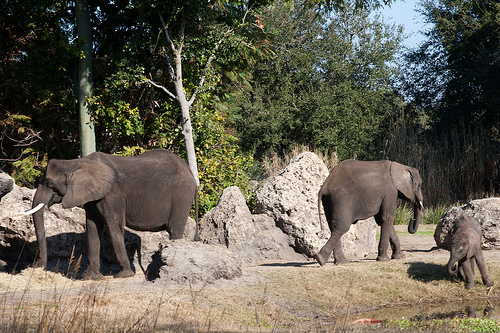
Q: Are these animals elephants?
A: Yes, all the animals are elephants.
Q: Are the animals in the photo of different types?
A: No, all the animals are elephants.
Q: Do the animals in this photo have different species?
A: No, all the animals are elephants.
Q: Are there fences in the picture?
A: No, there are no fences.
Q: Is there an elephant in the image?
A: Yes, there is an elephant.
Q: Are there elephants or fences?
A: Yes, there is an elephant.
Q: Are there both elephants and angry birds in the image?
A: No, there is an elephant but no angry birds.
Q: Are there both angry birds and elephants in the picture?
A: No, there is an elephant but no angry birds.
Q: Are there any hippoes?
A: No, there are no hippoes.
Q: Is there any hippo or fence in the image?
A: No, there are no hippoes or fences.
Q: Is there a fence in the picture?
A: No, there are no fences.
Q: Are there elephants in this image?
A: Yes, there is an elephant.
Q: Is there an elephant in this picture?
A: Yes, there is an elephant.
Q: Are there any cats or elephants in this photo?
A: Yes, there is an elephant.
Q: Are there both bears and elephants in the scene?
A: No, there is an elephant but no bears.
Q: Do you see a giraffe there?
A: No, there are no giraffes.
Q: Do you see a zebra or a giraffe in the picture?
A: No, there are no giraffes or zebras.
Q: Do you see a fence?
A: No, there are no fences.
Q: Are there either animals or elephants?
A: Yes, there is an elephant.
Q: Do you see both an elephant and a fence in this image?
A: No, there is an elephant but no fences.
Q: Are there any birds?
A: No, there are no birds.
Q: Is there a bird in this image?
A: No, there are no birds.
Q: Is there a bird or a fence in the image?
A: No, there are no birds or fences.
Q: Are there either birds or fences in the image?
A: No, there are no birds or fences.